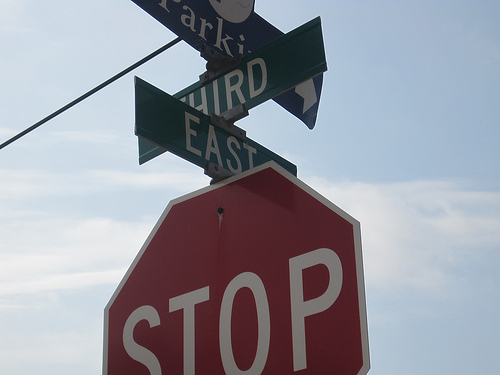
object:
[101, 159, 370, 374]
signpost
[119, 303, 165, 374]
letter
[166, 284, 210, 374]
letter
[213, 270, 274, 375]
letter o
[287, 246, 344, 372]
letter p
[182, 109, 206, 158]
letter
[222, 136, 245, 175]
letter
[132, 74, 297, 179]
sign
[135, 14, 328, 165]
sign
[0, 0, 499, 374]
cloud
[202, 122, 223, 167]
letter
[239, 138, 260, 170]
letter